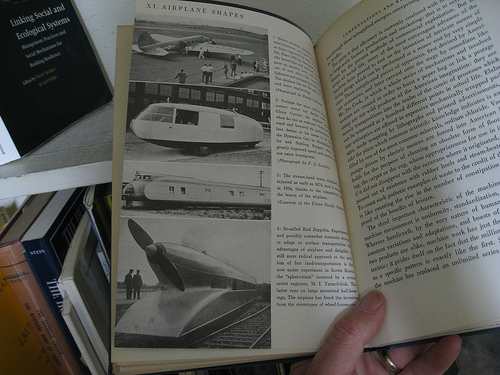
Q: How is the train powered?
A: Propeller.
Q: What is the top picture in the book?
A: Airplane.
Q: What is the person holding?
A: Book.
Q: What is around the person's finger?
A: Ring.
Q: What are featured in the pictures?
A: Vehicles.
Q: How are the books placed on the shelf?
A: Upright.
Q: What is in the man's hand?
A: Book.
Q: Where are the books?
A: Bookshelf.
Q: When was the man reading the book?
A: Weekday during work hours.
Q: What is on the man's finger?
A: A wedding band.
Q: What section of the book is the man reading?
A: Airplane shapes.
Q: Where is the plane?
A: Airport.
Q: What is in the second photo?
A: Car.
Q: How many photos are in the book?
A: 4.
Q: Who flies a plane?
A: Pilot.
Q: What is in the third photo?
A: Locamotive.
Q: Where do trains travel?
A: On tracks.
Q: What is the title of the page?
A: Airplane Shapes.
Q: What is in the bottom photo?
A: Train.